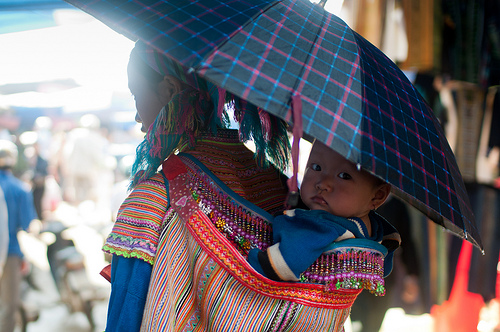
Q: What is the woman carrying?
A: A baby.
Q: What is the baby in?
A: A bag.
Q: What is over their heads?
A: Umbrella.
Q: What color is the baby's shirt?
A: Blue.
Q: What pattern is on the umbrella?
A: Plaid.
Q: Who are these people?
A: Mother and child.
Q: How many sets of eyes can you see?
A: One.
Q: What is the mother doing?
A: Walking.